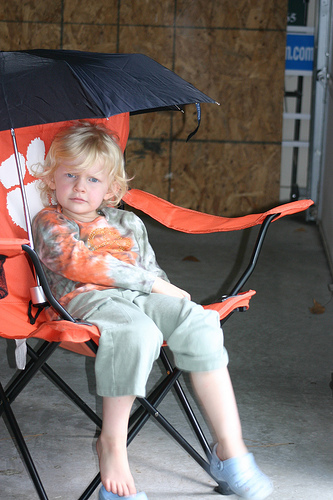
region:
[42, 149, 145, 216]
the head of a boy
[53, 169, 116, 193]
the eyes of a boy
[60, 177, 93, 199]
the nose of a boy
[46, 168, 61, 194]
the ear of a boy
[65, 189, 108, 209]
the lips of a boy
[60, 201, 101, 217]
the chin of a boy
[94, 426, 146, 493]
the foot of a boy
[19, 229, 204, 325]
the arm of a boy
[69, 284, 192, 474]
the leg of a boy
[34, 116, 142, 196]
the hair of a boy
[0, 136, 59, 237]
Picture of a bear paw on the back of the chair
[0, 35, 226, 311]
Black umbrella covering the child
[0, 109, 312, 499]
Orange, black and white folding chair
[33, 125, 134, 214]
Child with blue eyes and blonde hair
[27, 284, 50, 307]
Silver handle on an umbrella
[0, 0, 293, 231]
Large piece of particle board on the back wall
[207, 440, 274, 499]
White plastic sandal shoe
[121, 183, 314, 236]
Flimsy armwrest on a chair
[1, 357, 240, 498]
Black legs on a folding chair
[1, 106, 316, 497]
A child sitting in a chair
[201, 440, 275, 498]
One shoe is white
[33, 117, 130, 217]
Child has blonde hair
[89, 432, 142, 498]
One foot is bare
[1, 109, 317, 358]
The chair's seat and arms are orange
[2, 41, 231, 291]
A black open umbrella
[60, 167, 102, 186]
A pair of blue eyes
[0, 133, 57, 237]
A white bear paw drawing on chair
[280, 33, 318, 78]
A blue and white sign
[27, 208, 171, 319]
Orange and gray long sleeved shirt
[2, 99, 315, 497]
a kid sits on an orange chair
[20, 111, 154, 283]
the kid is blonde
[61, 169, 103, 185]
eyes of kid are blue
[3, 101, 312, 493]
folded chair is orange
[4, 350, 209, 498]
legs of chair are black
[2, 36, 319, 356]
a black umbrella over a chair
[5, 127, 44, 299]
shaft of umbrella is silver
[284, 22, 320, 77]
a blue sign in front a door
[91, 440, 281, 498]
a pair of blue shoes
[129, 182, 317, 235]
restarm of chair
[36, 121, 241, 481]
blonde child in a clemson chair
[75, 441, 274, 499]
pair of light blue crocs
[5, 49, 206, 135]
black umbrella over child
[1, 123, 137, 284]
orange clemson folding chair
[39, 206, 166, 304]
orange grey and white shirt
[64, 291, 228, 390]
grey shorts worn by child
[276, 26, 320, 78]
blue and white .com sign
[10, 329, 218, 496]
black metal legs of chair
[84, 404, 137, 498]
bare foot of child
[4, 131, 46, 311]
silver handle of umbrella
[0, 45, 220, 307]
a black umbrella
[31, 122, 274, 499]
The child in the chair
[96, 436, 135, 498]
The bare foot of the child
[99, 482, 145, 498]
The sandal on the ground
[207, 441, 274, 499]
The blue sandal on the foot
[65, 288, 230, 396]
The grey pants on the child